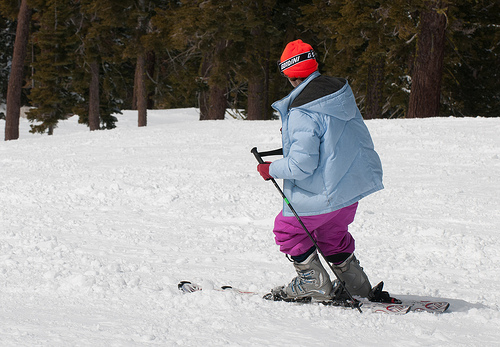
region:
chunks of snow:
[69, 245, 126, 287]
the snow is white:
[81, 249, 136, 300]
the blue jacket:
[296, 125, 373, 193]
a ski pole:
[275, 181, 302, 216]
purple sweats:
[278, 223, 305, 251]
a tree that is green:
[30, 44, 77, 128]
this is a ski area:
[25, 31, 472, 293]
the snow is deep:
[35, 158, 239, 316]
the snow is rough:
[57, 168, 237, 342]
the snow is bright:
[51, 164, 249, 334]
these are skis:
[182, 250, 419, 342]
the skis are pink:
[250, 197, 405, 272]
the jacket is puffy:
[272, 104, 399, 221]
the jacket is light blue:
[261, 81, 425, 229]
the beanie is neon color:
[281, 45, 362, 112]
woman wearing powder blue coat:
[267, 76, 389, 219]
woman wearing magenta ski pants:
[271, 198, 359, 258]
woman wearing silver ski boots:
[275, 256, 379, 301]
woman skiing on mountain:
[175, 35, 462, 333]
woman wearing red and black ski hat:
[277, 36, 319, 81]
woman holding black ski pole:
[245, 138, 361, 317]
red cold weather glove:
[257, 160, 272, 180]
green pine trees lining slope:
[7, 0, 498, 145]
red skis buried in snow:
[178, 270, 448, 325]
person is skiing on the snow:
[226, 25, 437, 330]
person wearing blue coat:
[233, 31, 401, 326]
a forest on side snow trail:
[7, 5, 494, 345]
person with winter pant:
[237, 25, 402, 323]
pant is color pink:
[258, 204, 358, 265]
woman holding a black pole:
[232, 26, 409, 318]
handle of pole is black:
[249, 139, 282, 194]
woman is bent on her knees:
[239, 25, 399, 315]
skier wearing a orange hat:
[251, 36, 373, 302]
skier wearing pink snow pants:
[251, 39, 379, 301]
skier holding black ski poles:
[250, 38, 381, 291]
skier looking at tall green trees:
[258, 37, 388, 299]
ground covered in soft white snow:
[0, 100, 497, 343]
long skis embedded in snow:
[173, 275, 494, 308]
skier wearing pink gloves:
[260, 32, 385, 293]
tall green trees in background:
[6, 2, 498, 140]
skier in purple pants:
[249, 35, 388, 311]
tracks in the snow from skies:
[164, 248, 283, 275]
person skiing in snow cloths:
[174, 40, 466, 315]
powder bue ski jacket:
[269, 71, 382, 213]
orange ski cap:
[277, 40, 319, 75]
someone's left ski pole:
[251, 149, 363, 313]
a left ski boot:
[281, 254, 340, 305]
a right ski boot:
[326, 259, 373, 298]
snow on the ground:
[74, 228, 132, 259]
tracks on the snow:
[151, 193, 225, 222]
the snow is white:
[425, 209, 460, 231]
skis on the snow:
[372, 305, 442, 319]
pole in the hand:
[272, 179, 310, 232]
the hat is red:
[275, 38, 322, 71]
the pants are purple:
[280, 219, 307, 244]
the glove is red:
[256, 160, 270, 175]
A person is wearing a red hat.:
[276, 36, 314, 80]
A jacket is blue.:
[261, 73, 382, 214]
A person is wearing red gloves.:
[257, 160, 272, 180]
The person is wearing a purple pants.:
[266, 202, 356, 262]